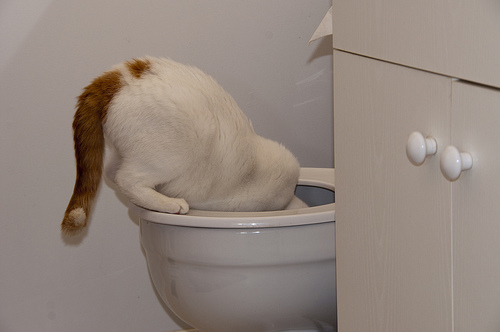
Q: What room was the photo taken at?
A: It was taken at the bathroom.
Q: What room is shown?
A: It is a bathroom.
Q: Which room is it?
A: It is a bathroom.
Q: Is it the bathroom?
A: Yes, it is the bathroom.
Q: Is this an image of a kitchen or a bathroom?
A: It is showing a bathroom.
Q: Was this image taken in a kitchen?
A: No, the picture was taken in a bathroom.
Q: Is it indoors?
A: Yes, it is indoors.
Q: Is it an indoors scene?
A: Yes, it is indoors.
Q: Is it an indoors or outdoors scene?
A: It is indoors.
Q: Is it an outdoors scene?
A: No, it is indoors.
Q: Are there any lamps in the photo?
A: No, there are no lamps.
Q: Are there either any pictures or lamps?
A: No, there are no lamps or pictures.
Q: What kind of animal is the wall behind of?
A: The wall is behind the cat.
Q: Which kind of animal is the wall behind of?
A: The wall is behind the cat.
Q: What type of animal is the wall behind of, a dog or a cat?
A: The wall is behind a cat.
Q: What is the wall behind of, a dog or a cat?
A: The wall is behind a cat.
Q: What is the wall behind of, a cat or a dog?
A: The wall is behind a cat.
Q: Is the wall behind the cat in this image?
A: Yes, the wall is behind the cat.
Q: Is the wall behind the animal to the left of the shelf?
A: Yes, the wall is behind the cat.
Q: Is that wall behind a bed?
A: No, the wall is behind the cat.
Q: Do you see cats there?
A: Yes, there is a cat.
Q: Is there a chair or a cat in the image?
A: Yes, there is a cat.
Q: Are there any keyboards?
A: No, there are no keyboards.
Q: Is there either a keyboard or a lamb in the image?
A: No, there are no keyboards or lambs.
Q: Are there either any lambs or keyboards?
A: No, there are no keyboards or lambs.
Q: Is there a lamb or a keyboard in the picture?
A: No, there are no keyboards or lambs.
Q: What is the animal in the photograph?
A: The animal is a cat.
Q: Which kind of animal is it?
A: The animal is a cat.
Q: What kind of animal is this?
A: That is a cat.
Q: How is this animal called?
A: That is a cat.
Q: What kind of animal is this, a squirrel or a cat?
A: That is a cat.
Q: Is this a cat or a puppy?
A: This is a cat.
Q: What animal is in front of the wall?
A: The cat is in front of the wall.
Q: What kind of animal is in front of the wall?
A: The animal is a cat.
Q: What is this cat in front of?
A: The cat is in front of the wall.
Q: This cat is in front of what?
A: The cat is in front of the wall.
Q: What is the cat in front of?
A: The cat is in front of the wall.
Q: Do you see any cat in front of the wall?
A: Yes, there is a cat in front of the wall.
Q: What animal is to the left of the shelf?
A: The animal is a cat.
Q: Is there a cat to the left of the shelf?
A: Yes, there is a cat to the left of the shelf.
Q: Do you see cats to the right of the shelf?
A: No, the cat is to the left of the shelf.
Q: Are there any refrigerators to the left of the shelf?
A: No, there is a cat to the left of the shelf.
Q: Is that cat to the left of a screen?
A: No, the cat is to the left of the shelf.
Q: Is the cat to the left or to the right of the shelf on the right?
A: The cat is to the left of the shelf.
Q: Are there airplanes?
A: No, there are no airplanes.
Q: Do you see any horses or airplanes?
A: No, there are no airplanes or horses.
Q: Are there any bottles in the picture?
A: No, there are no bottles.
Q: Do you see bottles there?
A: No, there are no bottles.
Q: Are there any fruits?
A: No, there are no fruits.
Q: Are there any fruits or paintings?
A: No, there are no fruits or paintings.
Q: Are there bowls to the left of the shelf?
A: Yes, there is a bowl to the left of the shelf.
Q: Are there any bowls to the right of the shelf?
A: No, the bowl is to the left of the shelf.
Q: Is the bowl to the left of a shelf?
A: Yes, the bowl is to the left of a shelf.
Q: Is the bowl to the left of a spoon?
A: No, the bowl is to the left of a shelf.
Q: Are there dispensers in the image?
A: No, there are no dispensers.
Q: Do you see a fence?
A: No, there are no fences.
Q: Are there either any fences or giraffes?
A: No, there are no fences or giraffes.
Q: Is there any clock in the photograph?
A: No, there are no clocks.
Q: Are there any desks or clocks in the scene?
A: No, there are no clocks or desks.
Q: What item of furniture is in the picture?
A: The piece of furniture is a shelf.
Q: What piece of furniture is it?
A: The piece of furniture is a shelf.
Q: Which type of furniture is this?
A: That is a shelf.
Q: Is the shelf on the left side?
A: No, the shelf is on the right of the image.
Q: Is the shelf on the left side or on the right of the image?
A: The shelf is on the right of the image.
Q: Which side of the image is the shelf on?
A: The shelf is on the right of the image.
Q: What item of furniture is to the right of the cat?
A: The piece of furniture is a shelf.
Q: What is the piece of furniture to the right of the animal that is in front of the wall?
A: The piece of furniture is a shelf.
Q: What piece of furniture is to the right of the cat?
A: The piece of furniture is a shelf.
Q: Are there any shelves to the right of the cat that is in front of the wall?
A: Yes, there is a shelf to the right of the cat.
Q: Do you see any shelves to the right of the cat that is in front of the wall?
A: Yes, there is a shelf to the right of the cat.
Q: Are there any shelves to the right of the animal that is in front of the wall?
A: Yes, there is a shelf to the right of the cat.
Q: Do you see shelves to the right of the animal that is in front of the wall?
A: Yes, there is a shelf to the right of the cat.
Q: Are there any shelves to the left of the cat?
A: No, the shelf is to the right of the cat.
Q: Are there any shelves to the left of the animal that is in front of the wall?
A: No, the shelf is to the right of the cat.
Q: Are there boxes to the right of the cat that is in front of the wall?
A: No, there is a shelf to the right of the cat.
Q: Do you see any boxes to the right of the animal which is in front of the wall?
A: No, there is a shelf to the right of the cat.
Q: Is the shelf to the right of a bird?
A: No, the shelf is to the right of the cat.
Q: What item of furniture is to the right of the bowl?
A: The piece of furniture is a shelf.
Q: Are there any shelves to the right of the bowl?
A: Yes, there is a shelf to the right of the bowl.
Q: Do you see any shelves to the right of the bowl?
A: Yes, there is a shelf to the right of the bowl.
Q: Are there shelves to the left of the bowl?
A: No, the shelf is to the right of the bowl.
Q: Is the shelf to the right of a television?
A: No, the shelf is to the right of the bowl.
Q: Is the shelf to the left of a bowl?
A: No, the shelf is to the right of a bowl.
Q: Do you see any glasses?
A: No, there are no glasses.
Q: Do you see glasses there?
A: No, there are no glasses.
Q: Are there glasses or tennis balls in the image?
A: No, there are no glasses or tennis balls.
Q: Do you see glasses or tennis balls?
A: No, there are no glasses or tennis balls.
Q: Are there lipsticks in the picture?
A: No, there are no lipsticks.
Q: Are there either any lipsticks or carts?
A: No, there are no lipsticks or carts.